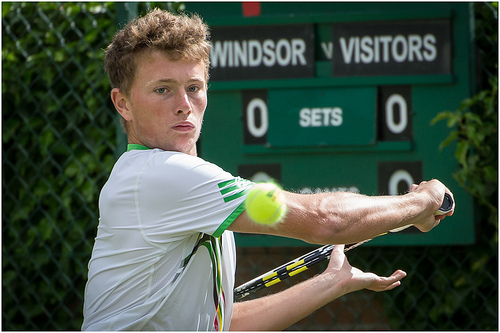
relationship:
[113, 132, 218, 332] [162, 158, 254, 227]
shirt has sleeve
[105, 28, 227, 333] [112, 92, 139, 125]
man has right ear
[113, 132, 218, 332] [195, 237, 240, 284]
shirt has stripes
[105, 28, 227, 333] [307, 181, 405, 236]
man has arm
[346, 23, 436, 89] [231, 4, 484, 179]
visitors on scoreboard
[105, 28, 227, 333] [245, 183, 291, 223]
man watching tennis ball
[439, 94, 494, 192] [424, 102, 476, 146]
tree has leaves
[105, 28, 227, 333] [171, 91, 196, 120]
man has nose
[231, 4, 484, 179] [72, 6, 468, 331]
scoreboard for tennis game